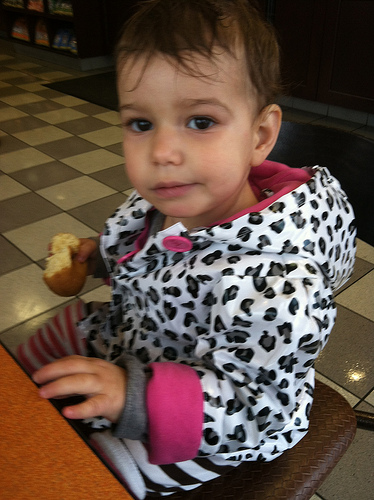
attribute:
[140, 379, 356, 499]
chair — brown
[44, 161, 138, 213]
floor — tiled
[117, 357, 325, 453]
sleeves — rolled up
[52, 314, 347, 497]
seat — brown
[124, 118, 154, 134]
eye — brown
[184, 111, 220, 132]
eye — brown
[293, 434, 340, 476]
seat — brown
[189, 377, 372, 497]
seat — brown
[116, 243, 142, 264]
button — second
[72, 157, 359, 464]
coat — white, black, pink, print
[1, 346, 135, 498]
table — brown, wooden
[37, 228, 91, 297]
doughnut — half-eaten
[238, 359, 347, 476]
seat — brown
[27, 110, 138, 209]
floor — tiled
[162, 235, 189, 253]
button — pink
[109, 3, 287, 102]
hair — brown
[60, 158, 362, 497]
jacket — black, white, pink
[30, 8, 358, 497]
girl — young